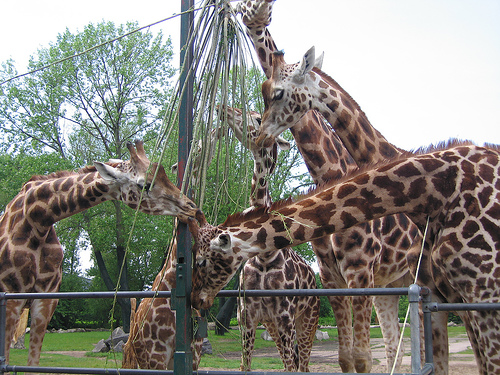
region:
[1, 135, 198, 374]
A giraffe in an enclosure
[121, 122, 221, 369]
A giraffe in an enclosure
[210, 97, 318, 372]
A giraffe in an enclosure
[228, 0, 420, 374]
A giraffe in an enclosure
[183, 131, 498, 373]
A giraffe in an enclosure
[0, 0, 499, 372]
A group of giraffes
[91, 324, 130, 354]
some rocks at the base of a tree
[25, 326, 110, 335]
A line of rocks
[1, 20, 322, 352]
some large trees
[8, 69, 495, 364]
the giraffes are six in total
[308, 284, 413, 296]
the fence is mettalic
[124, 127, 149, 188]
the horns are short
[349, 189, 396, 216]
the spots are brown and white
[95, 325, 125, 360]
the rocks are grey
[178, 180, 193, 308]
the pole is mettalic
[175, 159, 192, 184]
red spot is own the metal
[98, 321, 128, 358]
the rocks have a pointy top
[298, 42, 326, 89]
the ears are white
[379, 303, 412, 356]
the leg is brown and white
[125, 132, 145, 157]
The horns on the head of the giraffe on the left.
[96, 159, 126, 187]
The left ear of the giraffe on the left.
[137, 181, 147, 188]
The eye of the giraffe on the left.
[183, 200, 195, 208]
The nose of the giraffe on the left.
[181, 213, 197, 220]
The mouth of the giraffe on the left.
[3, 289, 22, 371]
The front left leg of the giraffe on the left.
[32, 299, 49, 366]
The front right leg of the giraffe on the left.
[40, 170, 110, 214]
The neck of the giraffe on the left.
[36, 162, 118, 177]
The mane on the neck of the giraffe on the left.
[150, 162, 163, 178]
The bump in the center of the giraffe's head on the left.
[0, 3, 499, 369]
a group of giraffes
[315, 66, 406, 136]
brown hair running along the neck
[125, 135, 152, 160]
two small horns on the top of the head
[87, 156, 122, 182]
ear on the side of the head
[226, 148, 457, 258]
dark brown spots on the neck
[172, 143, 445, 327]
head is bent down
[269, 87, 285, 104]
eye on the side of the head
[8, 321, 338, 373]
green grass on the ground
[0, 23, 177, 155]
green leaves on the tree branches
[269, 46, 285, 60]
top of the horn is black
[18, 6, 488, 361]
animals in a wildlife park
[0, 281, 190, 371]
metal bars and pole of a railing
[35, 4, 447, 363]
six giraffes standing together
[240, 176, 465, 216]
long spotted neck of a giraffe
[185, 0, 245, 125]
tree branches with foliage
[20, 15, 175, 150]
spreading tree against the sky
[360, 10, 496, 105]
overcast sky above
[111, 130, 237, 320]
animals nibbling on green buds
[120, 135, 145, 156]
a giraffe's ossicones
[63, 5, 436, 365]
giraffes gather for feeding